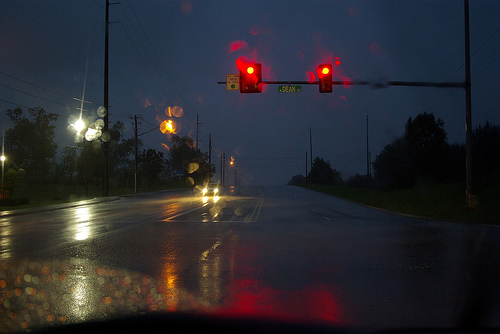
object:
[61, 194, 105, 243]
light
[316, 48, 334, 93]
traffic light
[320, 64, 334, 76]
red light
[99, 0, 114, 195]
powerline pole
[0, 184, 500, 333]
road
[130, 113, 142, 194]
powerline pole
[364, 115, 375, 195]
powerline pole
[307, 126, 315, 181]
powerline pole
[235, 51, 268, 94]
traffic light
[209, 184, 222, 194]
headlights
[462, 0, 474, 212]
pole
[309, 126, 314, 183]
pole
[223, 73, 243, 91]
sign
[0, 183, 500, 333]
ground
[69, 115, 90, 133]
glare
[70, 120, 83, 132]
lights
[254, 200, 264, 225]
lines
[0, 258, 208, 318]
water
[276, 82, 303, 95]
road sign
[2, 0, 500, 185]
sky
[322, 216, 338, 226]
line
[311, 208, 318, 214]
line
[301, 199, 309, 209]
line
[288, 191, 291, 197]
line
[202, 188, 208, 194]
headlight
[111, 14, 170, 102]
skies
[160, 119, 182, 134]
street light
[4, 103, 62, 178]
tree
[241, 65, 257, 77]
light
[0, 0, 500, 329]
dashboard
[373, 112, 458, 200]
trees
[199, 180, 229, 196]
car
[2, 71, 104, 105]
telephone lines